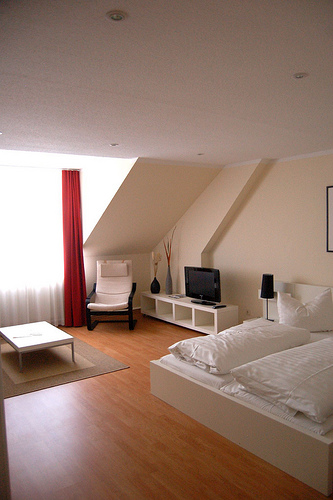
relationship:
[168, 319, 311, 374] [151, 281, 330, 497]
pillow on bed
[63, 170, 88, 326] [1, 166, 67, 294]
curtains on side of window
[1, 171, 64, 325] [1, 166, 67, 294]
sheer curtains covering window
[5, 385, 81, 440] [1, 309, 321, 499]
light reflecting on floor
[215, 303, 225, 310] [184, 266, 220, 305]
remote next to tv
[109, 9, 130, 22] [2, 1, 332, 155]
recessed lighting in ceiling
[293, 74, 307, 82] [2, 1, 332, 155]
recessed lighting on ceiling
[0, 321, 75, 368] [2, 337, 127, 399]
table on carpet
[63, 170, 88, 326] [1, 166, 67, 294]
curtains over window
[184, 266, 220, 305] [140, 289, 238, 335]
tv on stand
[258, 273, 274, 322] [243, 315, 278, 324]
lamp on nightstand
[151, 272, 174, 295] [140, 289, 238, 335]
vases on stand